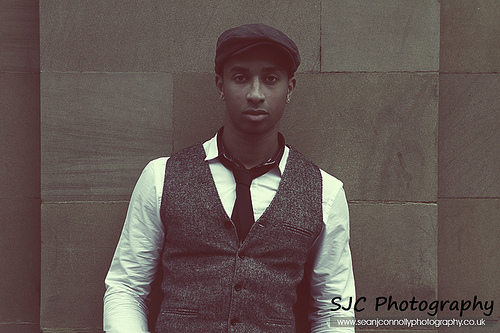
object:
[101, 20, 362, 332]
man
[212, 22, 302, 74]
hat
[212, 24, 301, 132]
head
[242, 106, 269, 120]
mouth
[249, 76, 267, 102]
nose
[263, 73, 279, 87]
eye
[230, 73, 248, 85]
eye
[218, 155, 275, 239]
tie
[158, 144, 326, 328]
vest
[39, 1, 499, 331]
wall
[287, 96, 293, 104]
earring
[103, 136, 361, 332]
shirt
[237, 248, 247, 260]
button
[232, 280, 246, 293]
button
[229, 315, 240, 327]
button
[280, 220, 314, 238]
pocket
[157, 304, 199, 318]
pocket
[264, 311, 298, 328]
pocket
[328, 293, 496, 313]
name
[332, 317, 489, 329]
website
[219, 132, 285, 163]
neck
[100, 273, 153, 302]
elbow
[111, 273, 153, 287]
wrinkle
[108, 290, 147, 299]
wrinkle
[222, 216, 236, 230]
button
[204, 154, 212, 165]
tip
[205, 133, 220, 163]
collar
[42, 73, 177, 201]
block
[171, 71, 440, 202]
block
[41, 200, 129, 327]
block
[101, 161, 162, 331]
sleeve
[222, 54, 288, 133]
face